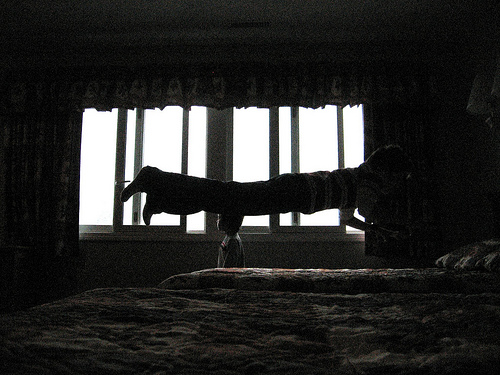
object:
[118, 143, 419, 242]
man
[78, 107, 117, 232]
light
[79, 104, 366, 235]
window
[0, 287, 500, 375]
bed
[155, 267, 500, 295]
bed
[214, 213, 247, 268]
boy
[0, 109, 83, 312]
curtain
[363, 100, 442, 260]
curtain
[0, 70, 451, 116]
valance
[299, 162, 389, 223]
shirt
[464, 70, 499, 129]
lamp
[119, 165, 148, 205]
foot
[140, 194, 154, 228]
foot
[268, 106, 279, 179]
wood strip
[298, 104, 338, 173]
light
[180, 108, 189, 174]
wood strip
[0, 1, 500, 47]
ceiling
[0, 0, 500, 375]
bedroom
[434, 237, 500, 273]
pillow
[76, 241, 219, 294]
wall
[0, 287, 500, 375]
blanket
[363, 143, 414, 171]
hair